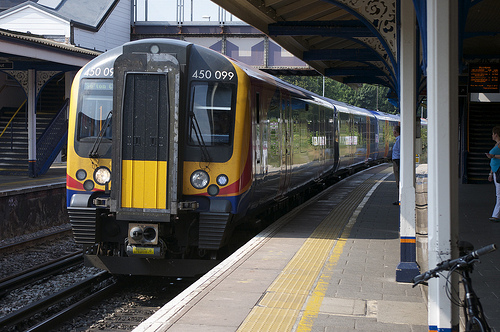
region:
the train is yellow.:
[55, 25, 391, 232]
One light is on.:
[73, 156, 233, 199]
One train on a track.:
[17, 27, 407, 291]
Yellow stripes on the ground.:
[254, 180, 388, 327]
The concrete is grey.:
[194, 226, 261, 330]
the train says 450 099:
[174, 52, 240, 92]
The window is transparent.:
[61, 44, 242, 191]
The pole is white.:
[412, 30, 460, 327]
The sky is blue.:
[132, 1, 267, 34]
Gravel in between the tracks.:
[11, 228, 106, 329]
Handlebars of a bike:
[400, 237, 477, 329]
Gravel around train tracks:
[38, 272, 91, 301]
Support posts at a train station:
[379, 31, 427, 267]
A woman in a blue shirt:
[474, 118, 498, 187]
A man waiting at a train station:
[370, 115, 417, 205]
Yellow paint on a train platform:
[259, 182, 374, 323]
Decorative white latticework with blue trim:
[9, 59, 68, 99]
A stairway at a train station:
[0, 84, 80, 163]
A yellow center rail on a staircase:
[2, 91, 39, 138]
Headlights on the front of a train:
[90, 164, 213, 189]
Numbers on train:
[186, 60, 243, 95]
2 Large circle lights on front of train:
[70, 152, 242, 216]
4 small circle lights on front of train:
[75, 160, 232, 202]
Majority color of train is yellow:
[65, 51, 259, 235]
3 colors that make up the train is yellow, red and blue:
[71, 49, 286, 255]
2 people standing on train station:
[369, 103, 499, 243]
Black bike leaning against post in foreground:
[411, 240, 499, 329]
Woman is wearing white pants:
[479, 122, 499, 227]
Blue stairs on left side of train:
[8, 79, 70, 191]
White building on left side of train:
[6, 10, 136, 54]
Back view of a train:
[65, 27, 263, 272]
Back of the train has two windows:
[61, 61, 252, 176]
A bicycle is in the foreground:
[375, 217, 496, 322]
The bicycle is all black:
[395, 230, 490, 325]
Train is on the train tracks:
[16, 205, 227, 330]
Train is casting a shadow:
[235, 120, 405, 250]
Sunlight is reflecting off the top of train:
[60, 46, 125, 121]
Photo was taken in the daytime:
[17, 7, 487, 302]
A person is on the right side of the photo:
[476, 122, 496, 218]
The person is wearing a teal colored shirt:
[476, 123, 499, 175]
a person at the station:
[387, 117, 411, 203]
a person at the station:
[483, 127, 499, 214]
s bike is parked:
[410, 243, 494, 327]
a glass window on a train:
[185, 77, 231, 147]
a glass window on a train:
[80, 80, 113, 142]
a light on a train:
[188, 170, 208, 190]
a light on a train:
[214, 170, 230, 186]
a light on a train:
[205, 182, 225, 199]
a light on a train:
[90, 160, 112, 184]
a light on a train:
[73, 166, 88, 180]